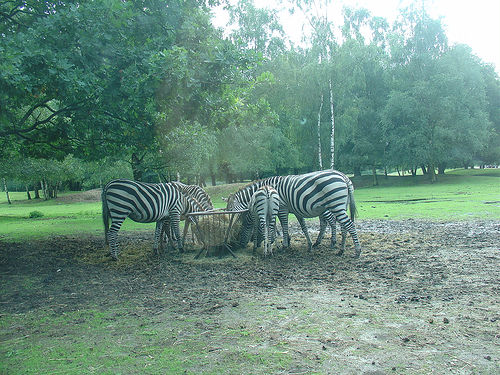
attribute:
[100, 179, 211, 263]
zebra — mature, adult, striped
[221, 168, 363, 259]
zebra — striped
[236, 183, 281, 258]
zebra — young, striped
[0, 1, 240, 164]
leaves — green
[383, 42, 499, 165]
leaves — green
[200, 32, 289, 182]
leaves — green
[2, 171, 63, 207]
trees — brown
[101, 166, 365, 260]
zebras — eating, gathered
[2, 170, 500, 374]
grass — patchy, green, brown, short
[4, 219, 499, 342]
dirt — disturbed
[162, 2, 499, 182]
trees — green, distant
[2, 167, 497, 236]
green grass — short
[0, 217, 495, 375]
brown grass — short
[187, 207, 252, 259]
trough — metal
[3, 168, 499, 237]
field — grassy